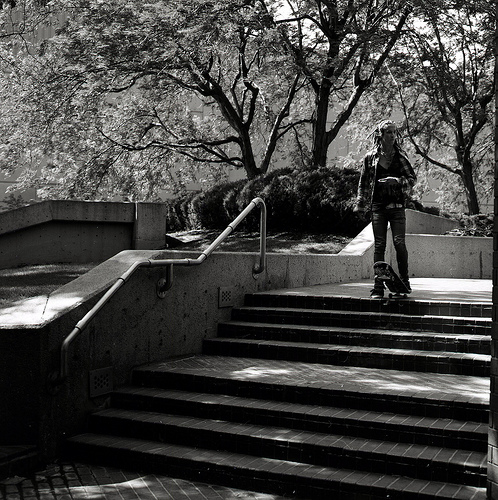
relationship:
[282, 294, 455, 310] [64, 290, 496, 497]
border on stairs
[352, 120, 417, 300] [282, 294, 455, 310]
boy on border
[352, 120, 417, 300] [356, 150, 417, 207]
boy wears shirt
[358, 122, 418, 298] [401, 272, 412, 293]
boy has feet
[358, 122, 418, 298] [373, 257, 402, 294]
boy holds skater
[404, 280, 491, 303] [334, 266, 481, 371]
shadows on ground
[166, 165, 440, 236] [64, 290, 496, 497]
bushes on side of stairs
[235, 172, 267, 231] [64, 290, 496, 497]
bushes on side of stairs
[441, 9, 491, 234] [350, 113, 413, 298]
tree behind boy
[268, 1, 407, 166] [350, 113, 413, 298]
tree behind boy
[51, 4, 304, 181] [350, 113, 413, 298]
tree behind boy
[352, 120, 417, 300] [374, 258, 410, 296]
boy has skateboard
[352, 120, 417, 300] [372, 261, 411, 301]
boy has skateboard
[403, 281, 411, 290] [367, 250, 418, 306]
feet holding skateboard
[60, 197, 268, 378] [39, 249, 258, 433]
rail on side side stairs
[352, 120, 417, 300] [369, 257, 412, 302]
boy standing on skateboard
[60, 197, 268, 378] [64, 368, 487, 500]
rail on side of stairs